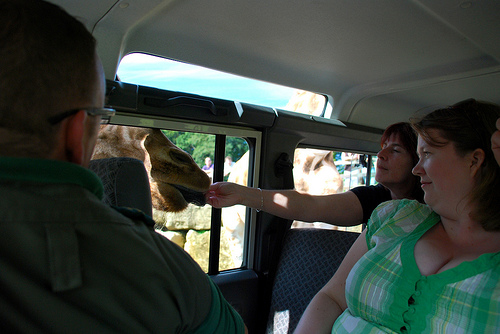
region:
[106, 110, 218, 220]
a giraffe with his nose in the window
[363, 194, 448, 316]
woman's green and white shirt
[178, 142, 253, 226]
a hand touching the giraffe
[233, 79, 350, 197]
body of the giraffe outside the window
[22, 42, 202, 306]
man wearing glasses and coat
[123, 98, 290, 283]
the side window of the car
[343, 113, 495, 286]
two women sitting in the car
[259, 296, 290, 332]
glare from the sun hitting the seat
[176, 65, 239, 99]
blue cloudy sky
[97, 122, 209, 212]
the giraffe sticking its head in the window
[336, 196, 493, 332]
the green and white shirt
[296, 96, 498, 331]
the woman in the green and white shirt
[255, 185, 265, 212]
the bracelet of the arm feeding the giraffe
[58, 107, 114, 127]
the glasses on the man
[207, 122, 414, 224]
the woman feeding the giraffe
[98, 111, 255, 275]
the opened window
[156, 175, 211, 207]
the mouth of the giraffe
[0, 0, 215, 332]
the man looking at the giraffe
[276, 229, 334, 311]
the seat of the car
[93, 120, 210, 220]
a giraffe's snout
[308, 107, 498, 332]
a woman sitting in car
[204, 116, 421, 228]
a woman sitting in car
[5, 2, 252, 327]
a man sitting in car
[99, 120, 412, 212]
woman feeding giraffe from car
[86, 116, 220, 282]
an open vehicle window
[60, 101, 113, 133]
a pair of black eyeglasses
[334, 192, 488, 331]
a green and white blouse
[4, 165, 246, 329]
a dark green shirt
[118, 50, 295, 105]
a cloudy blue sky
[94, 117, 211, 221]
Animal being fed.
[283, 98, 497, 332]
Woman watching animals in the car.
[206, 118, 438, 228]
Woman feeding animal from the backseat.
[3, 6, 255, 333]
Man watching animal being fed.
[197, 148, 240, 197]
People in the background.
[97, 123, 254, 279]
Window open to feed animal.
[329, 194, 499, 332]
Green and white shirt on woman.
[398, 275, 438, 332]
Buttons being stretched to their limit.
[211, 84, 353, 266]
Another animal in the background.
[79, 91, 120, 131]
Man wearing glasses.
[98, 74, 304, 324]
the window is open